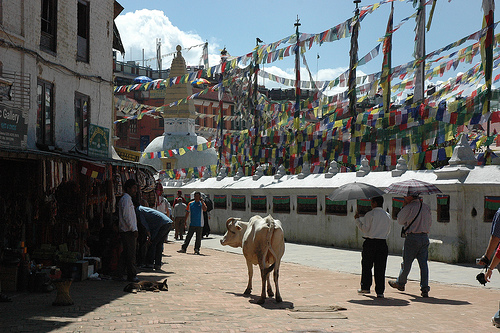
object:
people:
[93, 176, 215, 274]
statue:
[155, 42, 208, 181]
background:
[199, 48, 223, 71]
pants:
[356, 236, 390, 294]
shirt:
[356, 209, 395, 244]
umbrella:
[326, 178, 387, 202]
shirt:
[186, 202, 207, 229]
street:
[171, 283, 224, 329]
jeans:
[143, 247, 165, 265]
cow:
[223, 217, 285, 295]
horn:
[224, 215, 238, 232]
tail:
[258, 222, 279, 277]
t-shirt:
[122, 193, 136, 227]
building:
[1, 5, 110, 139]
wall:
[86, 1, 115, 130]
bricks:
[179, 294, 200, 315]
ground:
[105, 307, 493, 333]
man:
[354, 179, 392, 299]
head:
[371, 194, 385, 207]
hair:
[370, 196, 381, 203]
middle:
[197, 276, 219, 305]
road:
[306, 247, 341, 308]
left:
[215, 231, 220, 253]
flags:
[259, 96, 421, 146]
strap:
[413, 208, 422, 224]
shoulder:
[396, 202, 438, 208]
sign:
[83, 124, 112, 162]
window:
[77, 13, 90, 57]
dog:
[121, 277, 171, 293]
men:
[389, 178, 432, 299]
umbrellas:
[383, 174, 440, 201]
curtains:
[215, 70, 310, 134]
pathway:
[293, 245, 335, 267]